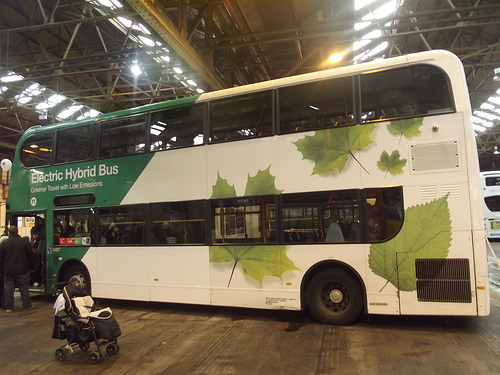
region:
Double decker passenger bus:
[7, 46, 492, 331]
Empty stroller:
[38, 274, 130, 364]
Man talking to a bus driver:
[1, 195, 47, 334]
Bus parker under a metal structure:
[2, 0, 498, 328]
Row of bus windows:
[1, 60, 481, 170]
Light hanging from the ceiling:
[118, 50, 192, 89]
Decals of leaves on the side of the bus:
[207, 102, 465, 322]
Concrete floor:
[120, 299, 376, 369]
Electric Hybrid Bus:
[1, 47, 491, 337]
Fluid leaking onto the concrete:
[267, 302, 322, 340]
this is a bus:
[110, 110, 447, 305]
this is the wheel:
[309, 267, 347, 315]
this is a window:
[206, 102, 290, 132]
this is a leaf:
[398, 225, 436, 267]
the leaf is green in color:
[416, 215, 427, 235]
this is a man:
[7, 225, 32, 291]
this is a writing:
[29, 169, 106, 181]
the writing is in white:
[36, 166, 123, 183]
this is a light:
[126, 62, 148, 77]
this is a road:
[194, 325, 283, 362]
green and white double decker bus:
[9, 68, 491, 342]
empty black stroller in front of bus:
[47, 260, 131, 362]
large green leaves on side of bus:
[203, 123, 470, 298]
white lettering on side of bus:
[28, 159, 128, 193]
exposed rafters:
[5, 24, 481, 99]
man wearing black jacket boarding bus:
[1, 204, 29, 281]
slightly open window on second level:
[93, 108, 162, 161]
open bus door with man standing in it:
[1, 199, 48, 294]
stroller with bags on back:
[49, 273, 123, 361]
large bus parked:
[0, 29, 485, 368]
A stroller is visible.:
[48, 264, 118, 368]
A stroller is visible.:
[48, 244, 165, 372]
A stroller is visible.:
[57, 256, 139, 341]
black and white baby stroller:
[49, 282, 121, 363]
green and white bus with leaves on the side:
[3, 48, 490, 325]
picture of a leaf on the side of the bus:
[366, 189, 453, 294]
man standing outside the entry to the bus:
[0, 223, 35, 312]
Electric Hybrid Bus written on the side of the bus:
[26, 162, 120, 185]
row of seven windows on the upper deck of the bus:
[18, 60, 458, 171]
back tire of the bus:
[303, 265, 367, 326]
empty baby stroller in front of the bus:
[51, 282, 120, 362]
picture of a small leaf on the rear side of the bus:
[378, 149, 408, 178]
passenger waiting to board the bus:
[0, 222, 33, 314]